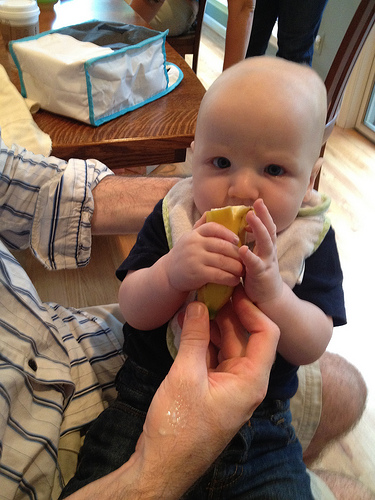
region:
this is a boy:
[103, 60, 340, 459]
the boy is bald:
[222, 55, 324, 160]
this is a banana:
[207, 210, 247, 315]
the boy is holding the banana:
[159, 193, 293, 326]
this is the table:
[121, 117, 171, 148]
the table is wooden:
[152, 102, 177, 143]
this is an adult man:
[0, 160, 73, 478]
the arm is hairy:
[105, 181, 144, 201]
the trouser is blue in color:
[252, 445, 300, 493]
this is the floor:
[342, 132, 367, 206]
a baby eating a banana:
[128, 54, 329, 393]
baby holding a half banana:
[179, 186, 284, 307]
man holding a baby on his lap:
[0, 54, 338, 496]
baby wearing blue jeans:
[98, 365, 301, 498]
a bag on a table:
[7, 21, 193, 116]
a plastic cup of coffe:
[2, 3, 41, 45]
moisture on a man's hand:
[156, 379, 212, 454]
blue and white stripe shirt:
[1, 138, 101, 493]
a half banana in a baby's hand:
[205, 205, 248, 307]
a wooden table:
[55, 84, 195, 172]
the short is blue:
[228, 413, 294, 493]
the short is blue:
[238, 392, 268, 471]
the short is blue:
[248, 424, 310, 488]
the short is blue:
[243, 431, 273, 462]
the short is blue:
[244, 447, 278, 466]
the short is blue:
[246, 403, 286, 442]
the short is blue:
[223, 388, 275, 457]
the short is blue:
[252, 405, 290, 484]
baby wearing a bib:
[68, 35, 336, 491]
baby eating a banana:
[111, 47, 333, 486]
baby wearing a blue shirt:
[63, 27, 343, 493]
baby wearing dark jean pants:
[71, 19, 338, 483]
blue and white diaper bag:
[11, 14, 182, 121]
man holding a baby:
[3, 148, 360, 482]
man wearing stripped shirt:
[1, 148, 357, 493]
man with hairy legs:
[4, 150, 352, 493]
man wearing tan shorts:
[2, 148, 365, 487]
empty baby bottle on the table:
[3, 6, 45, 76]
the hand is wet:
[152, 379, 305, 474]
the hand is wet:
[156, 371, 216, 444]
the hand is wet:
[153, 376, 231, 487]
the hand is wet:
[108, 360, 209, 432]